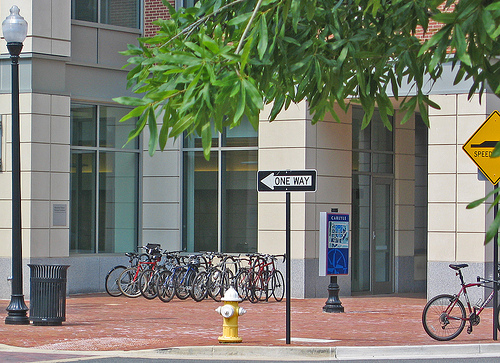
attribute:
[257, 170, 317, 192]
sign — black, white, one way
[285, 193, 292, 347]
pole — dark, colored, black, metal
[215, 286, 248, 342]
hydrant — yellow, white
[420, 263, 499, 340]
bike — red, parked, black, locked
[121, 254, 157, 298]
bike — red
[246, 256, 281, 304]
bike — red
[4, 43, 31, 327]
pole — huge, metal, decorative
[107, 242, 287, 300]
group — large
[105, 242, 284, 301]
bikes — parked, chained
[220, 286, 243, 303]
top — white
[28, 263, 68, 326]
trashcan — large, metal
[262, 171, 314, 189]
arrow — white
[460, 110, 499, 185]
sign — yellow, black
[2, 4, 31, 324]
lamp — tall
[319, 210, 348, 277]
sign — blue, white, informative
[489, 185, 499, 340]
post — metal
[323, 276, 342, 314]
post — metal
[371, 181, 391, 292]
door — glass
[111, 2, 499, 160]
leaves — green, lush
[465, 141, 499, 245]
leaves — green